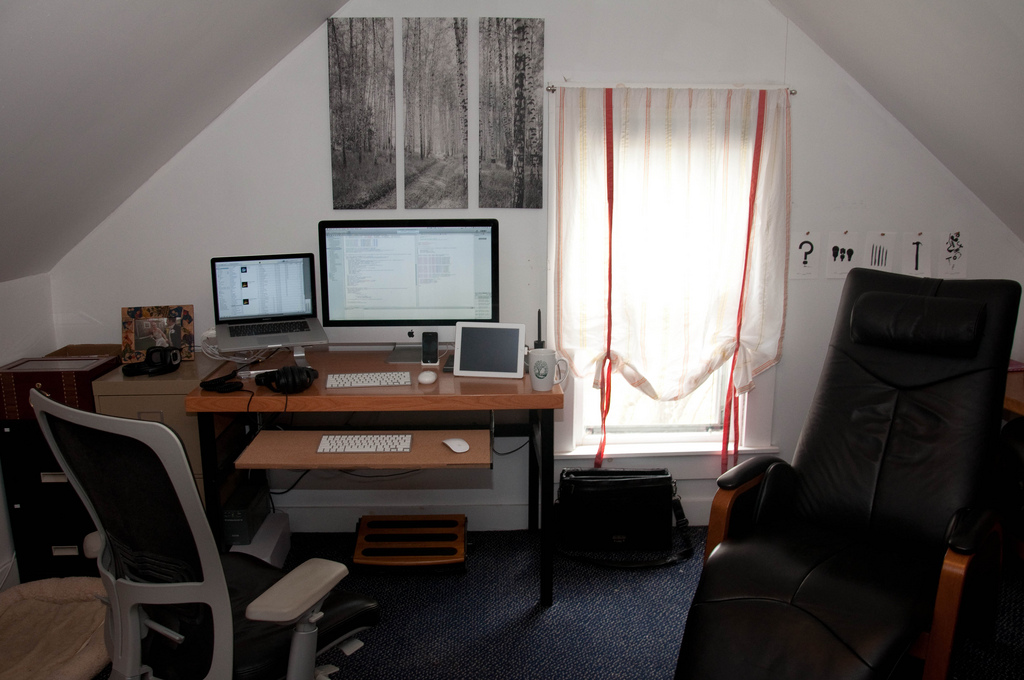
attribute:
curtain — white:
[555, 90, 791, 427]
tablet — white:
[454, 318, 525, 377]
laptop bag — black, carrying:
[550, 461, 688, 575]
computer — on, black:
[318, 220, 499, 360]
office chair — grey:
[24, 387, 375, 676]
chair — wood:
[682, 268, 1022, 676]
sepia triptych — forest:
[328, 15, 545, 212]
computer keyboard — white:
[315, 431, 414, 457]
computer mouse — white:
[445, 436, 471, 453]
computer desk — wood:
[187, 344, 564, 607]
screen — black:
[464, 329, 514, 379]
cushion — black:
[215, 539, 283, 604]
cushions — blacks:
[761, 280, 986, 672]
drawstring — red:
[590, 80, 772, 448]